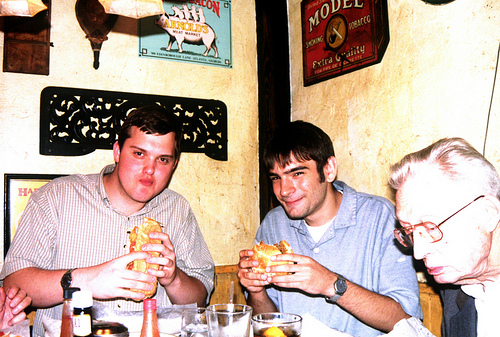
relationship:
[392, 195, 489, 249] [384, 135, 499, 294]
eyeglasses on elderly man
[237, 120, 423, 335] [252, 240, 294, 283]
man holding sandwich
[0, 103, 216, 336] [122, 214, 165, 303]
man eating bread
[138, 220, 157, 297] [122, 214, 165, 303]
bread on bread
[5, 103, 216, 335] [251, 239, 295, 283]
man holding sandwich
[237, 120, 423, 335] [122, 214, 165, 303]
man holding bread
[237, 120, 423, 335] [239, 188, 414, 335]
man wearing shirt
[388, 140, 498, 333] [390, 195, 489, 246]
man wearing eyeglasses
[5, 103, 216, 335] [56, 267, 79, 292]
man wearing watch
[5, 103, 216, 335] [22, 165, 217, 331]
man wearing shirt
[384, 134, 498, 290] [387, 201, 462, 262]
man wearing glasses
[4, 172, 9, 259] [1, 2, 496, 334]
black frame on picture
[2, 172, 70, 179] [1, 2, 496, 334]
black frame on picture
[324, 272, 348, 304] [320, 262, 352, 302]
watch on wrist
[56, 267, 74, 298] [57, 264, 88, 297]
watch on wrist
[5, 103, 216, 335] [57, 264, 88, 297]
man has wrist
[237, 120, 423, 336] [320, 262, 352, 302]
man has wrist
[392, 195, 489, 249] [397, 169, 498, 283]
eyeglasses on man`s face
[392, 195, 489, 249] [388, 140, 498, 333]
eyeglasses on man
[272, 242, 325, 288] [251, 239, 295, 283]
hand has sandwich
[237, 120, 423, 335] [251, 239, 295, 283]
man has sandwich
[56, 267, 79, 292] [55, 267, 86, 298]
watch on wrist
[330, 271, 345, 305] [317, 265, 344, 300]
watch on wrist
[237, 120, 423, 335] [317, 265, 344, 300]
man has wrist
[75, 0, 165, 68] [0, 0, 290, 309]
light on wall